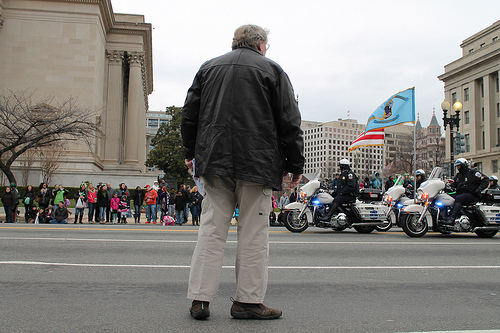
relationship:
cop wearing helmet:
[439, 157, 490, 228] [452, 157, 468, 167]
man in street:
[176, 22, 307, 322] [2, 218, 499, 330]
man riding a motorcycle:
[318, 157, 360, 222] [282, 168, 395, 233]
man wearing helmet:
[316, 157, 359, 224] [318, 156, 360, 174]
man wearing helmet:
[176, 22, 307, 322] [335, 157, 351, 167]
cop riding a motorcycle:
[443, 157, 491, 229] [396, 166, 498, 234]